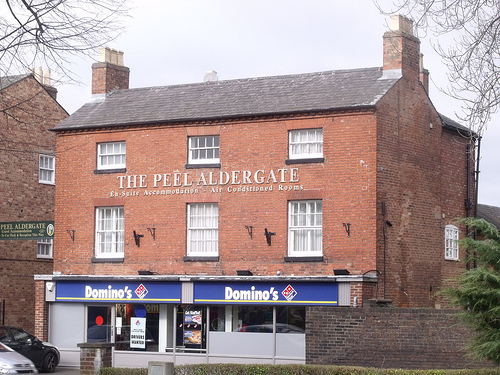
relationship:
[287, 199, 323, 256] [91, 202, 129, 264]
curtains are covering a curtains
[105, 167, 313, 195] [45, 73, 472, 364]
letters are on side of a building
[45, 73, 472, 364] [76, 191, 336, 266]
building has three windows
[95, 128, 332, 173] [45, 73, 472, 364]
three windows on are building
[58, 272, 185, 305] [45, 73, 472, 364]
sign on front of a building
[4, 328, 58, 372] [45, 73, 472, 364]
car in front of building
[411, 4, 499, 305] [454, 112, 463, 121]
tree has no leaves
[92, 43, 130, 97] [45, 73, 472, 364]
chimney on top of building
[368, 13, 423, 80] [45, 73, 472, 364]
chimney on building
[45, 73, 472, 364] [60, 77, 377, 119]
building has a shingled roof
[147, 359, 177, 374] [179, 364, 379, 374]
garbage can sitting by a hedge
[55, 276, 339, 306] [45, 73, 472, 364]
domino's signs are hanging on a building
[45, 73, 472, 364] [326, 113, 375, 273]
building made of brick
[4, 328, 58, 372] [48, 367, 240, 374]
car are parked on sidewalk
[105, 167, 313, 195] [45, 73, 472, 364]
letters are on building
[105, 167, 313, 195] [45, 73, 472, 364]
letters on building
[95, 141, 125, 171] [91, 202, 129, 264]
curtains are covering a curtains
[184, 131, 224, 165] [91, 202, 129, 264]
curtains are covering a curtains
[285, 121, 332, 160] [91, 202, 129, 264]
curtains are covering a curtains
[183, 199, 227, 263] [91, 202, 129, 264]
curtains are covering a curtains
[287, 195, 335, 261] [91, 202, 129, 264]
curtains are covering a curtains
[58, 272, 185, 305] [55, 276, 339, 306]
sign made for domino's pizza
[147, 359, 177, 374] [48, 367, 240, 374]
trash can sitting on sidewalk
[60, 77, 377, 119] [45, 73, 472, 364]
roof on top of hotel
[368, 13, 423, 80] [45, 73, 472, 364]
chimney on top of building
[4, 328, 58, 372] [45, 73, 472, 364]
car are parked in front building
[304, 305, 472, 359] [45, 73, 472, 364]
wall next to hotel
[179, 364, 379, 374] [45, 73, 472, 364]
hedge in front of building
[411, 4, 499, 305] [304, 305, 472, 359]
tree beside wall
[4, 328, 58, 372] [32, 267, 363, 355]
car in front of store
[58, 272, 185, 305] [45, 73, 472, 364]
sign between building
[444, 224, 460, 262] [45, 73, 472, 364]
mullions on building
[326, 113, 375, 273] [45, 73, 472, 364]
brick on building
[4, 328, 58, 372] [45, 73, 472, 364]
car are next to building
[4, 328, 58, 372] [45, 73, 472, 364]
car are in front of building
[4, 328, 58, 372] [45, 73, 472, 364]
car between building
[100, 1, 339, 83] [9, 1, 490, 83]
clouds are in sky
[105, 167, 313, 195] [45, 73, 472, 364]
words are on front of building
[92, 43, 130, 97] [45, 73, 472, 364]
chimney sitting on building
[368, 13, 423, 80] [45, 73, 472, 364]
chimney sitting on building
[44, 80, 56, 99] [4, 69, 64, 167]
chimney on building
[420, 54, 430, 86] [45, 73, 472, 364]
chimney on building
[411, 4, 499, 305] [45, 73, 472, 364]
tree next to building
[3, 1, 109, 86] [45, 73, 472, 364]
tree next to building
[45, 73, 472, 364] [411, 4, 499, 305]
building next to tree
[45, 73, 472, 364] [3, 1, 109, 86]
building next to tree